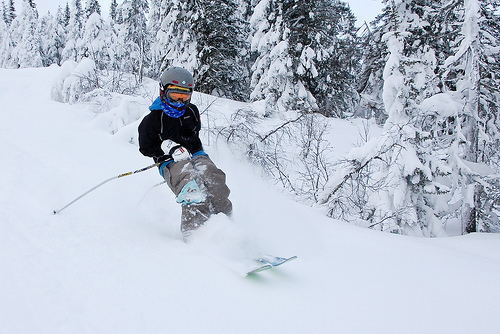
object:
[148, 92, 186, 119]
bandana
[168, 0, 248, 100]
tree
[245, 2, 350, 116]
tree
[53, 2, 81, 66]
tree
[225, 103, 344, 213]
brush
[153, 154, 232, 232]
pants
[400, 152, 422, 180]
ground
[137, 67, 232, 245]
guy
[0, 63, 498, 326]
hill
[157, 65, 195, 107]
helmet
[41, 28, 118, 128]
snow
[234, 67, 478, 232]
bushes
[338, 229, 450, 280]
snow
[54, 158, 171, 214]
ski pole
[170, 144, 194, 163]
skier's hand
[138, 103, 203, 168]
jacket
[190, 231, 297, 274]
skateboard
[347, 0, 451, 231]
trees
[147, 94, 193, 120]
hankerchief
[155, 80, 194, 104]
goggles